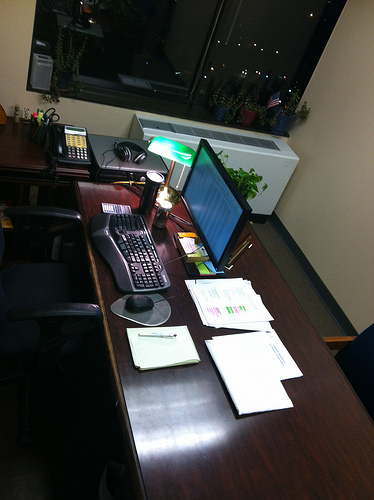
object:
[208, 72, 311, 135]
row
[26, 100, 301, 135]
windowsill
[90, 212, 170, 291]
keyboard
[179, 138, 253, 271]
monitor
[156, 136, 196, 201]
desk lamp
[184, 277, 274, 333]
stack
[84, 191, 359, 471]
desk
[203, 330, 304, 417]
stack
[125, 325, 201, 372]
stack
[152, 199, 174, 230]
can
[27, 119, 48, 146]
cup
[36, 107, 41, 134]
pen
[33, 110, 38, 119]
highlighter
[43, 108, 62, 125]
scissors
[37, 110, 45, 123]
highlighter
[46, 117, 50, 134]
pen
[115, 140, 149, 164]
headphone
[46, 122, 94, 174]
telephone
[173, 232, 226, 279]
tray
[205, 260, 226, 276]
sticky note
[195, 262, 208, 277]
sticky note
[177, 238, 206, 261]
business card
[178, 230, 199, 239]
sticky note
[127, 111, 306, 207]
air conditioning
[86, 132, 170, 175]
computer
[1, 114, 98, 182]
desk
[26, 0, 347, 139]
window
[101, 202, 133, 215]
calculator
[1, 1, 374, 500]
office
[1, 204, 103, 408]
computer chair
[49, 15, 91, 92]
plant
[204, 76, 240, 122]
plant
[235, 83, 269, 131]
plant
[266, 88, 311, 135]
plant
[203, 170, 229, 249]
spreadsheet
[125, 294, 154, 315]
computer mouse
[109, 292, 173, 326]
mouse pad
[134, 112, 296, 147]
top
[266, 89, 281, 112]
flag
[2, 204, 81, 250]
arm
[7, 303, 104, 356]
arm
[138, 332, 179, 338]
pen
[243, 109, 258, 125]
plant pot